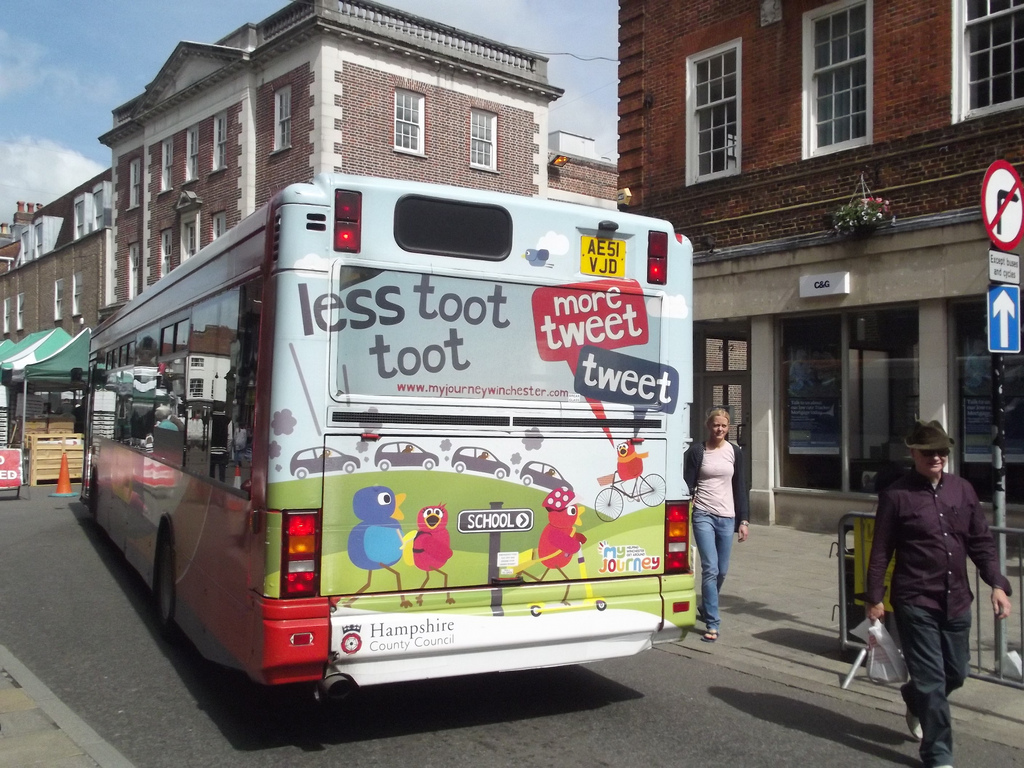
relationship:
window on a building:
[390, 78, 432, 163] [96, 3, 572, 274]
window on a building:
[464, 102, 501, 178] [310, 1, 576, 189]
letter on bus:
[297, 273, 321, 341] [77, 173, 710, 731]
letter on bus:
[312, 284, 354, 332] [77, 173, 710, 731]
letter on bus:
[414, 269, 441, 324] [77, 173, 710, 731]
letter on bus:
[375, 279, 406, 331] [77, 173, 710, 731]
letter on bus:
[394, 344, 425, 375] [77, 173, 710, 731]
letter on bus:
[345, 286, 378, 332] [77, 173, 710, 731]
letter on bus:
[464, 286, 490, 330] [77, 173, 710, 731]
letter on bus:
[298, 284, 314, 337] [77, 173, 710, 731]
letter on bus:
[413, 274, 438, 320] [77, 173, 710, 731]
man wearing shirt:
[860, 424, 992, 764] [853, 472, 992, 626]